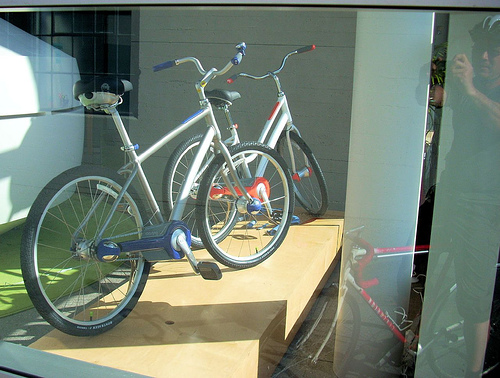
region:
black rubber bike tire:
[200, 140, 297, 272]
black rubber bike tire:
[21, 161, 156, 338]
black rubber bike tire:
[273, 130, 330, 218]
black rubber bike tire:
[162, 136, 241, 251]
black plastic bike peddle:
[193, 259, 223, 285]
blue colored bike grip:
[230, 51, 243, 66]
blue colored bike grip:
[149, 58, 178, 76]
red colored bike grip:
[295, 45, 315, 55]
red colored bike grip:
[227, 73, 244, 83]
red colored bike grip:
[353, 240, 380, 290]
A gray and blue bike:
[21, 41, 296, 338]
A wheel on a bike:
[18, 161, 151, 338]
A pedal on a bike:
[195, 259, 222, 280]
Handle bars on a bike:
[152, 41, 247, 88]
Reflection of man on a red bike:
[240, 13, 499, 377]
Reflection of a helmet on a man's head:
[468, 14, 498, 44]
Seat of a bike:
[70, 75, 139, 111]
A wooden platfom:
[30, 208, 351, 377]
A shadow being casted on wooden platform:
[29, 299, 291, 376]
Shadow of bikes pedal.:
[226, 231, 258, 241]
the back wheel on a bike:
[25, 141, 192, 317]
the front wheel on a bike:
[190, 110, 295, 281]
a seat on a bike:
[65, 50, 157, 140]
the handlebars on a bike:
[156, 33, 278, 85]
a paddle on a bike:
[176, 256, 226, 288]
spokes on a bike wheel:
[57, 168, 137, 273]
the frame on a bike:
[101, 55, 248, 265]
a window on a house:
[31, 0, 155, 155]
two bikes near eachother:
[29, 57, 369, 294]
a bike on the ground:
[29, 125, 202, 328]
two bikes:
[18, 43, 328, 336]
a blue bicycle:
[18, 46, 293, 336]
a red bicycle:
[188, 45, 330, 217]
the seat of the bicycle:
[73, 74, 135, 109]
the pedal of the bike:
[173, 228, 223, 278]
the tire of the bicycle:
[19, 163, 151, 335]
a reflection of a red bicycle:
[301, 226, 454, 374]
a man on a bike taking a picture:
[423, 17, 493, 374]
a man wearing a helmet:
[418, 15, 494, 376]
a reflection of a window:
[0, 8, 134, 115]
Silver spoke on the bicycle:
[40, 209, 82, 240]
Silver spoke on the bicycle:
[36, 232, 88, 267]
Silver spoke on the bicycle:
[45, 264, 85, 309]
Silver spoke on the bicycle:
[70, 258, 102, 313]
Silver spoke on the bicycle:
[74, 184, 113, 223]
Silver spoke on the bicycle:
[200, 171, 279, 241]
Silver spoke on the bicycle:
[240, 218, 277, 260]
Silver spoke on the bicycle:
[254, 161, 286, 200]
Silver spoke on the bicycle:
[280, 128, 325, 220]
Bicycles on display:
[23, 46, 345, 317]